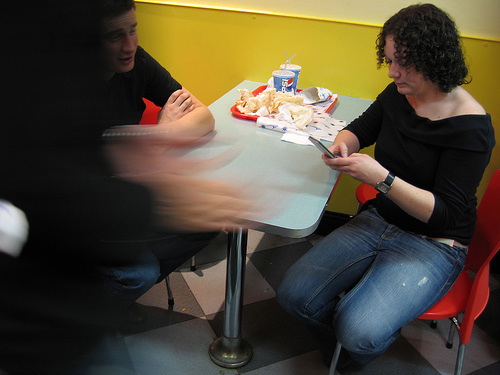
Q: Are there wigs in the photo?
A: No, there are no wigs.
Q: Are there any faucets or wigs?
A: No, there are no wigs or faucets.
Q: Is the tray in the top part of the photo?
A: Yes, the tray is in the top of the image.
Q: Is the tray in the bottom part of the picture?
A: No, the tray is in the top of the image.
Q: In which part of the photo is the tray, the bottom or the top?
A: The tray is in the top of the image.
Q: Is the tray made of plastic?
A: Yes, the tray is made of plastic.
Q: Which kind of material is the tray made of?
A: The tray is made of plastic.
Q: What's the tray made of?
A: The tray is made of plastic.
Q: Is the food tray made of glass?
A: No, the tray is made of plastic.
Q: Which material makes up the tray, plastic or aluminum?
A: The tray is made of plastic.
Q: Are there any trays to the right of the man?
A: Yes, there is a tray to the right of the man.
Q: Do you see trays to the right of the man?
A: Yes, there is a tray to the right of the man.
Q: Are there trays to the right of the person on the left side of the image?
A: Yes, there is a tray to the right of the man.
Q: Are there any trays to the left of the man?
A: No, the tray is to the right of the man.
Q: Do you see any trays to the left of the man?
A: No, the tray is to the right of the man.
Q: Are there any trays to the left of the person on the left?
A: No, the tray is to the right of the man.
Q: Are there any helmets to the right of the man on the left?
A: No, there is a tray to the right of the man.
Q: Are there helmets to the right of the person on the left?
A: No, there is a tray to the right of the man.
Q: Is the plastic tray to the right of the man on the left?
A: Yes, the tray is to the right of the man.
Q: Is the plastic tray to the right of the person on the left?
A: Yes, the tray is to the right of the man.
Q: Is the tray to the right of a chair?
A: No, the tray is to the right of the man.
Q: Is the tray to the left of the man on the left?
A: No, the tray is to the right of the man.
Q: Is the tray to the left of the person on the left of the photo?
A: No, the tray is to the right of the man.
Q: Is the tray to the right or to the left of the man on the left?
A: The tray is to the right of the man.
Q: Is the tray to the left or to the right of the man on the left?
A: The tray is to the right of the man.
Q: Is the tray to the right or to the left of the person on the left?
A: The tray is to the right of the man.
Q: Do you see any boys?
A: No, there are no boys.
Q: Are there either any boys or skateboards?
A: No, there are no boys or skateboards.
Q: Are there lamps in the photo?
A: No, there are no lamps.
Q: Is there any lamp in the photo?
A: No, there are no lamps.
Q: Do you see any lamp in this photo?
A: No, there are no lamps.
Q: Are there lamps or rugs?
A: No, there are no lamps or rugs.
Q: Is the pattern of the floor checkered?
A: Yes, the floor is checkered.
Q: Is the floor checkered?
A: Yes, the floor is checkered.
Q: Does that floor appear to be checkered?
A: Yes, the floor is checkered.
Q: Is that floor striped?
A: No, the floor is checkered.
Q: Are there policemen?
A: No, there are no policemen.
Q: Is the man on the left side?
A: Yes, the man is on the left of the image.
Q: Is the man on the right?
A: No, the man is on the left of the image.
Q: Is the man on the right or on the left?
A: The man is on the left of the image.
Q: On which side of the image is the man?
A: The man is on the left of the image.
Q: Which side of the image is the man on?
A: The man is on the left of the image.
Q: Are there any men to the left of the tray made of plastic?
A: Yes, there is a man to the left of the tray.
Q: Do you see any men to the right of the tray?
A: No, the man is to the left of the tray.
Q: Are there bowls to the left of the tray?
A: No, there is a man to the left of the tray.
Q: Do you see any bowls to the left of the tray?
A: No, there is a man to the left of the tray.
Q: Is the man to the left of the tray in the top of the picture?
A: Yes, the man is to the left of the tray.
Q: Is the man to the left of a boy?
A: No, the man is to the left of the tray.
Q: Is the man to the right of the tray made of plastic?
A: No, the man is to the left of the tray.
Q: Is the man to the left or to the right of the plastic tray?
A: The man is to the left of the tray.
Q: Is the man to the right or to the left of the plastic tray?
A: The man is to the left of the tray.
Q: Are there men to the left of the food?
A: Yes, there is a man to the left of the food.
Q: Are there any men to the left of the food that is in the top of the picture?
A: Yes, there is a man to the left of the food.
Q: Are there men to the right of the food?
A: No, the man is to the left of the food.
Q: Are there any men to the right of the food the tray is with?
A: No, the man is to the left of the food.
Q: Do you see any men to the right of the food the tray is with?
A: No, the man is to the left of the food.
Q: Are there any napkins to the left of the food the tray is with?
A: No, there is a man to the left of the food.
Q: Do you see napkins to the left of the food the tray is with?
A: No, there is a man to the left of the food.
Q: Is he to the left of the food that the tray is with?
A: Yes, the man is to the left of the food.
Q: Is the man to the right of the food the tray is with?
A: No, the man is to the left of the food.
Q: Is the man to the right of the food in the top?
A: No, the man is to the left of the food.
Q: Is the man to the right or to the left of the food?
A: The man is to the left of the food.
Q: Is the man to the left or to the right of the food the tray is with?
A: The man is to the left of the food.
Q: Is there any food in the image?
A: Yes, there is food.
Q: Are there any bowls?
A: No, there are no bowls.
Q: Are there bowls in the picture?
A: No, there are no bowls.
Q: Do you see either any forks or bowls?
A: No, there are no bowls or forks.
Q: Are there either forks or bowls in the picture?
A: No, there are no bowls or forks.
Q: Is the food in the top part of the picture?
A: Yes, the food is in the top of the image.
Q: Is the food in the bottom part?
A: No, the food is in the top of the image.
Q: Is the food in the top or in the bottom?
A: The food is in the top of the image.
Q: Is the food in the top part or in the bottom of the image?
A: The food is in the top of the image.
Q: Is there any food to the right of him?
A: Yes, there is food to the right of the man.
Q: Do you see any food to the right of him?
A: Yes, there is food to the right of the man.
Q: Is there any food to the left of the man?
A: No, the food is to the right of the man.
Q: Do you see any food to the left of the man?
A: No, the food is to the right of the man.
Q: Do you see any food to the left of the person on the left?
A: No, the food is to the right of the man.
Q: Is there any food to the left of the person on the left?
A: No, the food is to the right of the man.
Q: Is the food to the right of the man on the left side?
A: Yes, the food is to the right of the man.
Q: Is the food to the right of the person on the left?
A: Yes, the food is to the right of the man.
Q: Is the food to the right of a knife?
A: No, the food is to the right of the man.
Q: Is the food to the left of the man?
A: No, the food is to the right of the man.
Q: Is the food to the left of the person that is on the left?
A: No, the food is to the right of the man.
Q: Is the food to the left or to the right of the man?
A: The food is to the right of the man.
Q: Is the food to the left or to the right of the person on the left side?
A: The food is to the right of the man.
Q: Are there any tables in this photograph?
A: Yes, there is a table.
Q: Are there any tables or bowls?
A: Yes, there is a table.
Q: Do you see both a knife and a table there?
A: No, there is a table but no knives.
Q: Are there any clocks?
A: No, there are no clocks.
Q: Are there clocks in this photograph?
A: No, there are no clocks.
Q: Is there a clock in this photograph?
A: No, there are no clocks.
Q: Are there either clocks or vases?
A: No, there are no clocks or vases.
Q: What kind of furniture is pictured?
A: The furniture is a table.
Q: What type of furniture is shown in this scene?
A: The furniture is a table.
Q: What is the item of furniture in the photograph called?
A: The piece of furniture is a table.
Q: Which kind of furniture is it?
A: The piece of furniture is a table.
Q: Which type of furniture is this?
A: This is a table.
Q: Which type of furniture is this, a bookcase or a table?
A: This is a table.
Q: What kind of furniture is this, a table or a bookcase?
A: This is a table.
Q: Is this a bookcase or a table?
A: This is a table.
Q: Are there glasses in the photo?
A: No, there are no glasses.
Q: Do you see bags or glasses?
A: No, there are no glasses or bags.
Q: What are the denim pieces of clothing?
A: The clothing items are jeans.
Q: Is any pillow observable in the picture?
A: No, there are no pillows.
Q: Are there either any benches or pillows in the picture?
A: No, there are no pillows or benches.